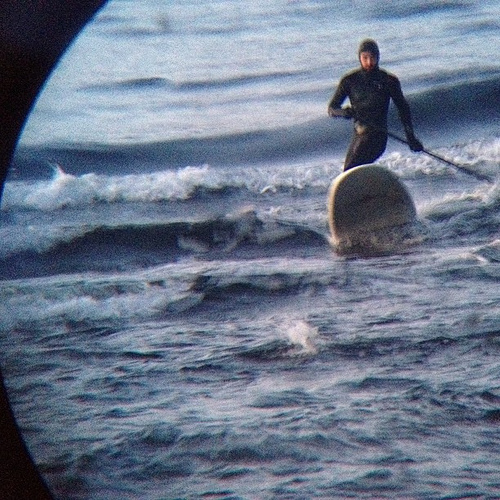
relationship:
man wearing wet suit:
[321, 38, 424, 167] [331, 30, 434, 166]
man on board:
[321, 38, 424, 167] [321, 160, 405, 234]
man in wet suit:
[321, 38, 424, 167] [331, 30, 434, 166]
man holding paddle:
[321, 38, 424, 167] [427, 147, 494, 194]